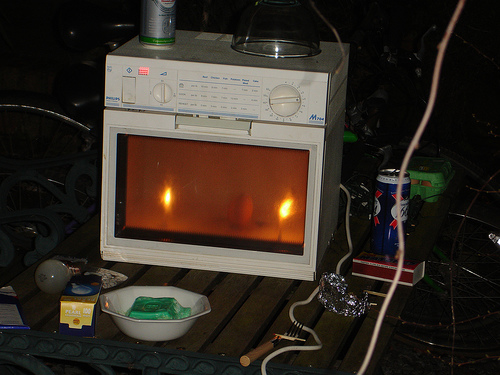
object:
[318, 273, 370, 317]
aluminum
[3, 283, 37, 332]
paper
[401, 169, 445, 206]
box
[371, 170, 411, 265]
beer can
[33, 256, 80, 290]
light bulb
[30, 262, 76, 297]
light bulb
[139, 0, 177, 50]
beer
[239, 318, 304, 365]
fork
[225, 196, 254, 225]
egg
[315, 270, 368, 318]
ball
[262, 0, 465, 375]
cord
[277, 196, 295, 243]
candle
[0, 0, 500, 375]
table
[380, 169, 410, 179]
top soda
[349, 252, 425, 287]
box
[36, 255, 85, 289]
lightbulb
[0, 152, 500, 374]
counter(table)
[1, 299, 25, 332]
wrapper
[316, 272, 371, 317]
foil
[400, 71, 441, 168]
wire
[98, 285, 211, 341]
bowl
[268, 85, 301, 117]
dial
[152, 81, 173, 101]
dial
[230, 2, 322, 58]
bowl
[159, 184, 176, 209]
flame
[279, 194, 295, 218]
flame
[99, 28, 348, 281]
appliance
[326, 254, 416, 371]
slat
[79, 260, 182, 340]
slat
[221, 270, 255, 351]
slat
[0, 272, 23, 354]
slat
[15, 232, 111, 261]
slat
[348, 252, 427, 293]
match box